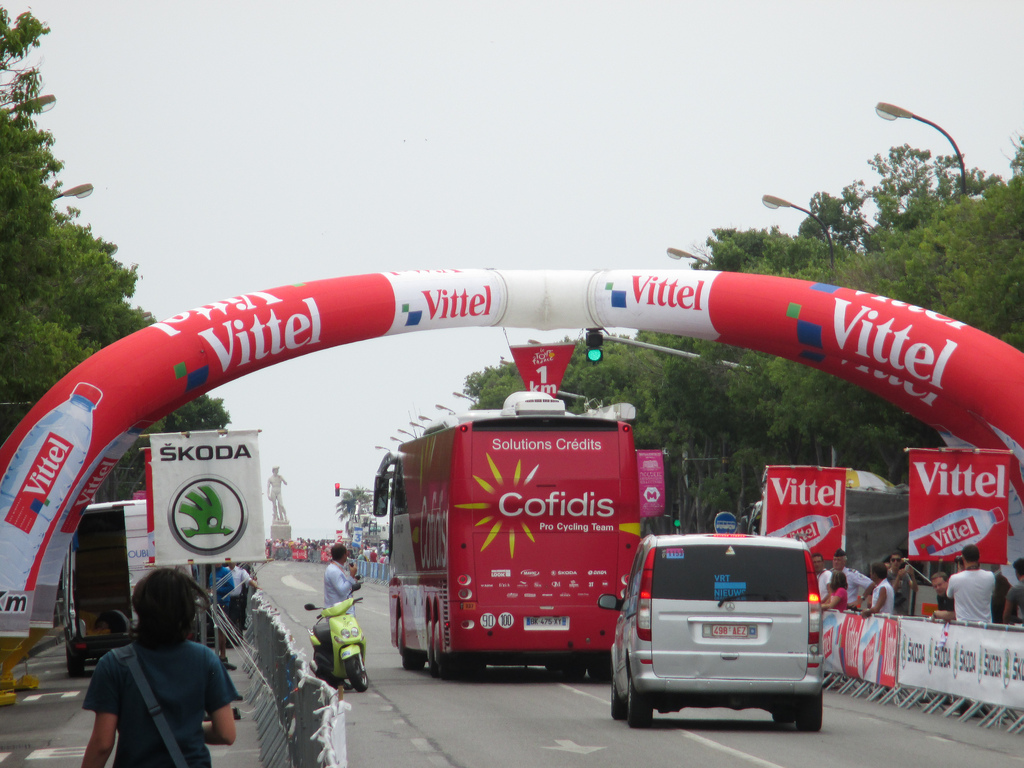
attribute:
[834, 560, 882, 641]
shirt — white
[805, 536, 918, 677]
shirt — white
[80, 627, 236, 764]
shirt — blue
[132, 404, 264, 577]
business logo — skoda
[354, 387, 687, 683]
city bus — big red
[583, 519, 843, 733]
suv — grey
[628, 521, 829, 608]
rear window — grey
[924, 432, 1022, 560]
business logo — vittel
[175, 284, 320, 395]
logo sign — vittel business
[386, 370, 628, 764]
bus — large red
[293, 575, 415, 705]
motorcycle — green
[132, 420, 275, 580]
flag — white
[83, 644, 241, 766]
shirt — black, blue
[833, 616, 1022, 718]
fence — white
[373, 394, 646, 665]
bus — red, double decker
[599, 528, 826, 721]
van — grey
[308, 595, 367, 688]
motorcycle — green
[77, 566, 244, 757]
woman — walking, sort sleeved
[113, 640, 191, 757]
strap — for bag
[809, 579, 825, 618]
light — orange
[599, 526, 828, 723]
car — silver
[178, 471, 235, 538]
logo — green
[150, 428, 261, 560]
sign — white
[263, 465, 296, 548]
statue — a man, white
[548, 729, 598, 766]
arrow — white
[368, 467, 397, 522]
mirror — rear view